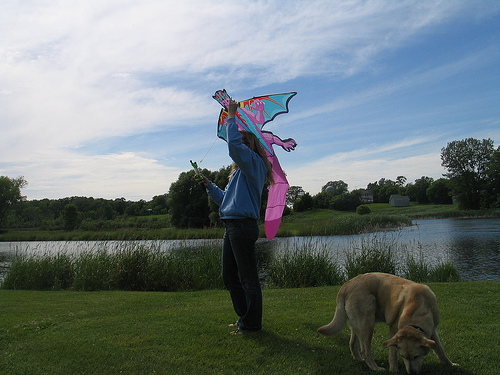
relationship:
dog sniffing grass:
[318, 270, 461, 374] [0, 287, 498, 374]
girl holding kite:
[192, 97, 273, 337] [212, 88, 298, 241]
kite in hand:
[212, 88, 298, 241] [226, 98, 240, 119]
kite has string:
[212, 88, 298, 241] [195, 130, 219, 167]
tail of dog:
[318, 297, 348, 335] [318, 270, 461, 374]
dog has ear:
[318, 270, 461, 374] [420, 334, 438, 352]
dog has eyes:
[318, 270, 461, 374] [400, 352, 423, 361]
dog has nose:
[318, 270, 461, 374] [405, 367, 416, 373]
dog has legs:
[318, 270, 461, 374] [343, 310, 388, 374]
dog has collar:
[318, 270, 461, 374] [400, 324, 434, 340]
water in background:
[1, 216, 499, 285] [1, 143, 496, 303]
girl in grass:
[192, 96, 272, 337] [0, 287, 498, 374]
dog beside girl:
[318, 270, 461, 374] [192, 96, 272, 337]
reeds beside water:
[2, 240, 462, 294] [1, 216, 499, 285]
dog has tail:
[318, 270, 461, 374] [318, 297, 348, 335]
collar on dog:
[400, 324, 434, 340] [318, 270, 461, 374]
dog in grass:
[318, 270, 461, 374] [0, 287, 498, 374]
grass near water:
[0, 287, 498, 374] [1, 216, 499, 285]